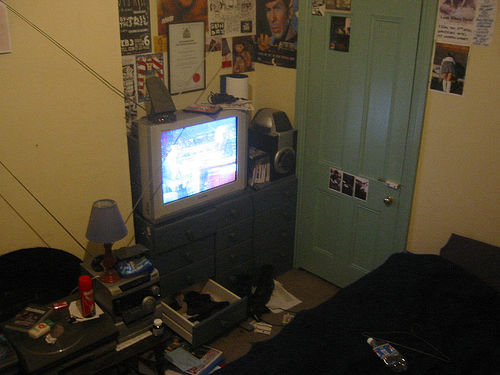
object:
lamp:
[84, 198, 128, 282]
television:
[134, 107, 254, 225]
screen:
[159, 116, 238, 204]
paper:
[328, 16, 352, 54]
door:
[292, 0, 435, 287]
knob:
[383, 196, 393, 206]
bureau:
[151, 178, 298, 303]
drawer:
[159, 279, 250, 335]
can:
[76, 274, 96, 318]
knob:
[186, 229, 193, 241]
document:
[167, 19, 207, 96]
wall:
[0, 0, 296, 254]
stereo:
[79, 252, 163, 342]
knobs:
[141, 294, 157, 313]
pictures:
[230, 33, 257, 75]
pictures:
[328, 167, 343, 193]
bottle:
[365, 336, 410, 372]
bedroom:
[0, 0, 495, 373]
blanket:
[210, 251, 500, 374]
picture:
[429, 42, 472, 96]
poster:
[255, 0, 297, 68]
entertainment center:
[0, 241, 180, 374]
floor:
[141, 269, 338, 375]